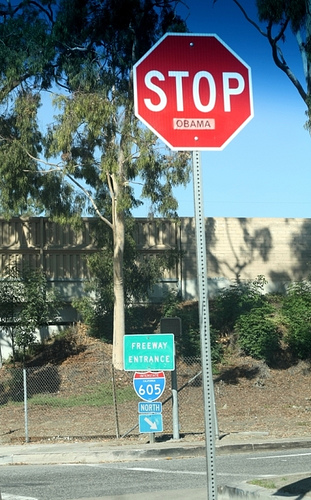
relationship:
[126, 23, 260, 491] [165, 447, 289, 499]
sign in corner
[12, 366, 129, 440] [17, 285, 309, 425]
fence around hill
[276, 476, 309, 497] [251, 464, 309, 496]
shadow on grass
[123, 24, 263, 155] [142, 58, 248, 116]
sign has lettering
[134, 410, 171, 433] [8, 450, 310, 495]
sign beside road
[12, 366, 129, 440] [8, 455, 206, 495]
fence near sidewalk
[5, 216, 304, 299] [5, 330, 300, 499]
building near intersection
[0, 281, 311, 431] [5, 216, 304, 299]
hill in front building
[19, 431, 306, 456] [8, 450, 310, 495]
curb next to road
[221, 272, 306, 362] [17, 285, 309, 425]
shrubs are on hill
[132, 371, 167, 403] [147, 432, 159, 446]
sign are on pole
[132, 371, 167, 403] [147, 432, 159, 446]
sign on pole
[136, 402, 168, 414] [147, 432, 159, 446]
sign on pole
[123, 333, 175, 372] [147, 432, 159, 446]
sign on pole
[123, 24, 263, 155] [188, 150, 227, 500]
sign attached to pole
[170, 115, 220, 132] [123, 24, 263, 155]
sticker attached to sign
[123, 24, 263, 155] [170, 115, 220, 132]
sign with message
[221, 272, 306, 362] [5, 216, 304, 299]
shrubs planted near wall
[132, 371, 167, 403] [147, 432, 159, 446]
sign attached to pole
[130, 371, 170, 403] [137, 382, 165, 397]
sign with a name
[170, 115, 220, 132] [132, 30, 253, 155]
sticker on sign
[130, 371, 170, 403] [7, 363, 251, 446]
sign attached to fence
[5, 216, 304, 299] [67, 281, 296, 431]
wall on top of hill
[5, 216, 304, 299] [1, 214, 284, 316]
shadows on wall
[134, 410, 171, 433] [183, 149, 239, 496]
sign on pole